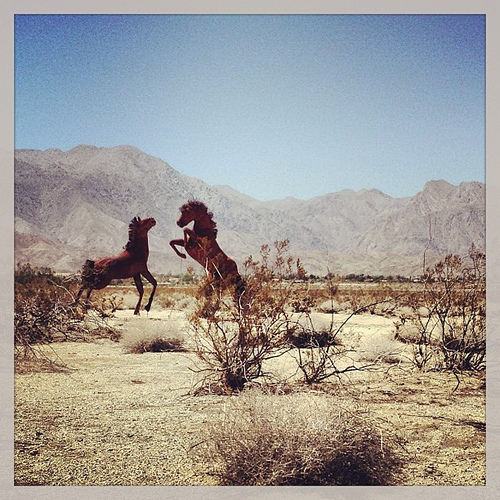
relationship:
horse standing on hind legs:
[169, 199, 243, 321] [196, 277, 224, 314]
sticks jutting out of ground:
[271, 300, 404, 382] [18, 272, 483, 482]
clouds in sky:
[208, 134, 294, 172] [177, 22, 377, 201]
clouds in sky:
[116, 53, 193, 103] [126, 20, 436, 146]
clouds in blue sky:
[168, 55, 241, 112] [74, 26, 451, 166]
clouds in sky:
[376, 97, 439, 142] [16, 19, 480, 201]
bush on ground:
[182, 382, 399, 495] [18, 272, 483, 482]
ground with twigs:
[18, 272, 483, 482] [281, 298, 377, 385]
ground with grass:
[18, 272, 483, 482] [19, 286, 484, 310]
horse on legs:
[172, 194, 247, 296] [203, 255, 244, 315]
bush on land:
[185, 243, 335, 398] [164, 293, 348, 442]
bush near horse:
[12, 264, 120, 361] [171, 197, 246, 324]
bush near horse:
[12, 264, 120, 361] [73, 216, 165, 319]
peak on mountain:
[21, 134, 175, 171] [17, 140, 476, 270]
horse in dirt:
[169, 199, 243, 321] [39, 267, 458, 472]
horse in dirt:
[72, 215, 156, 318] [39, 267, 458, 472]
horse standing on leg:
[63, 205, 182, 327] [83, 284, 93, 307]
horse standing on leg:
[63, 205, 182, 327] [71, 275, 81, 300]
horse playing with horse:
[72, 215, 156, 318] [169, 199, 255, 317]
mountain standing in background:
[17, 140, 476, 270] [13, 139, 481, 292]